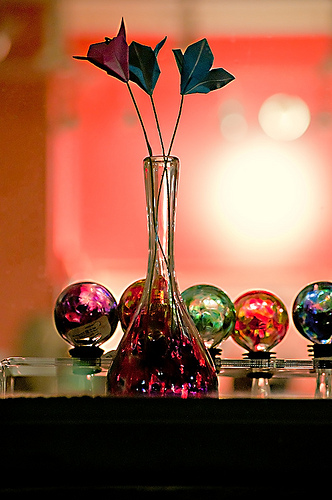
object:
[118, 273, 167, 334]
glass ball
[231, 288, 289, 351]
glass ball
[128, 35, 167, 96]
paper leafs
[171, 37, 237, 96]
paper leaves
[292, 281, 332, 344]
sphere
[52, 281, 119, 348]
ball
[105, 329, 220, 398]
base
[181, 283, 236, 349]
ball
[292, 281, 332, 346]
glass ball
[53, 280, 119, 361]
bulbs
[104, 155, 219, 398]
vase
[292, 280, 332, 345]
bulbs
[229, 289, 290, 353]
spheres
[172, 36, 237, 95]
flower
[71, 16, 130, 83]
flower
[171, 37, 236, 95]
paper